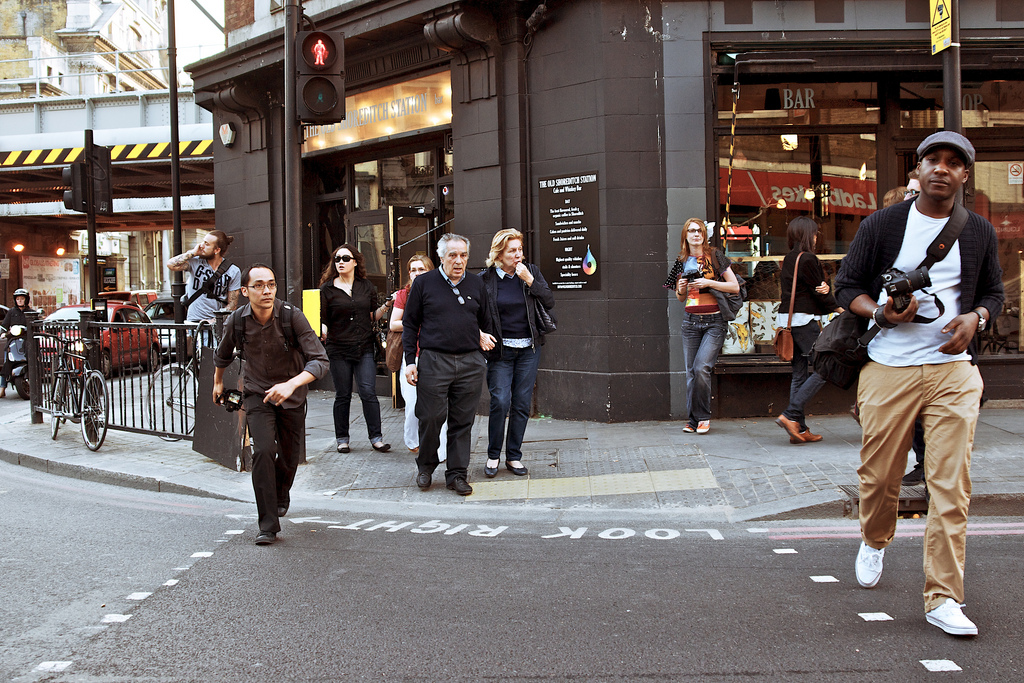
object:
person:
[392, 223, 481, 505]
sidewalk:
[280, 381, 1009, 509]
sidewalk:
[120, 376, 1021, 521]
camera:
[873, 263, 937, 309]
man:
[397, 229, 490, 502]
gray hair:
[433, 229, 472, 264]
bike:
[44, 347, 119, 452]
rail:
[25, 329, 197, 448]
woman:
[306, 229, 401, 465]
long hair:
[317, 242, 356, 278]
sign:
[537, 174, 606, 297]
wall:
[447, 16, 682, 431]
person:
[194, 261, 338, 542]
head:
[241, 267, 287, 320]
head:
[317, 245, 362, 274]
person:
[305, 247, 392, 457]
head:
[425, 229, 470, 277]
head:
[905, 133, 974, 197]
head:
[397, 247, 432, 274]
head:
[194, 230, 226, 256]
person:
[665, 219, 740, 429]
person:
[388, 253, 460, 459]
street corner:
[39, 465, 874, 666]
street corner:
[30, 446, 878, 676]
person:
[465, 225, 558, 480]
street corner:
[109, 441, 960, 677]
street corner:
[54, 454, 917, 677]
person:
[781, 212, 832, 449]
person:
[165, 227, 247, 375]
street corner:
[24, 458, 968, 672]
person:
[8, 285, 44, 363]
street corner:
[6, 420, 1016, 663]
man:
[833, 135, 1000, 644]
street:
[24, 480, 1018, 676]